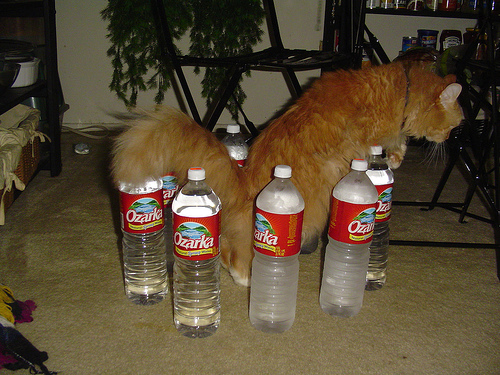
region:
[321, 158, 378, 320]
tall bottle of watter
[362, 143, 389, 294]
tall bottle of watter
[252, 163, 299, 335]
tall bottle of watter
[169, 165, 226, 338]
tall bottle of watter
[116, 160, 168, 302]
tall bottle of watter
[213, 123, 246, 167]
tall bottle of watter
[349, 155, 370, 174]
white cap on bottle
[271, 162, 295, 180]
white cap on bottle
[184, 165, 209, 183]
white cap on bottle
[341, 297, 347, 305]
part of a bottle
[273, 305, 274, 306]
edge of a bottle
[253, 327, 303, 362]
part of the floor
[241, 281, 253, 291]
side of a bottle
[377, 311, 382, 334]
edge of a floor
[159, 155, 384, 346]
Bottles of water have red labels.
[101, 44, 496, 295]
Cat has orange fur.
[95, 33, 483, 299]
Cat has long fur.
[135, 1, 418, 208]
Black chair behind cat.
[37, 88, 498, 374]
Room has a carpeted floor.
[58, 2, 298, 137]
Green plant near chair in back of room.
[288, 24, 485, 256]
Cat has dark colored collar on.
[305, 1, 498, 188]
Can goods on shelves near chair.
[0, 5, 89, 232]
Cookware on shelves near cat.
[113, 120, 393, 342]
Bottles on the floor.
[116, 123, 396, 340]
A bunch of water bottles.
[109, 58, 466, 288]
A cat jumping over bottles.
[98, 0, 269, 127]
A plant hanging down.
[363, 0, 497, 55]
Food on a shelf.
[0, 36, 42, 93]
Bowls on a shelf.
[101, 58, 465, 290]
An orange fluffy cat.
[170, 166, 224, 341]
A bottle with water in it.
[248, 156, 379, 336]
Two bottles of water.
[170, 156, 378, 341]
Three bottles of water.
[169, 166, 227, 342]
plastic water bottle sitting on floor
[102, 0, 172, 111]
green leaves hanging from plant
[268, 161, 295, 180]
white plastic top on water bottle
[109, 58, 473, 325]
orange cat behind water bottles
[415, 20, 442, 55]
plastic breadcrumb container on shelf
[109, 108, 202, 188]
orange hair on tail of cat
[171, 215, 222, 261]
company name on side of water bottle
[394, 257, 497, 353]
brown carpet on floor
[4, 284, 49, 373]
clothing laying on carpet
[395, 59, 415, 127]
collar on neck of cat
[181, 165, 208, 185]
Cap on a water bottle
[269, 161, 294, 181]
Cap on a water bottle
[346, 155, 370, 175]
Cap on a water bottle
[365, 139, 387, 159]
Cap on a water bottle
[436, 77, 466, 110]
Ear of a cat